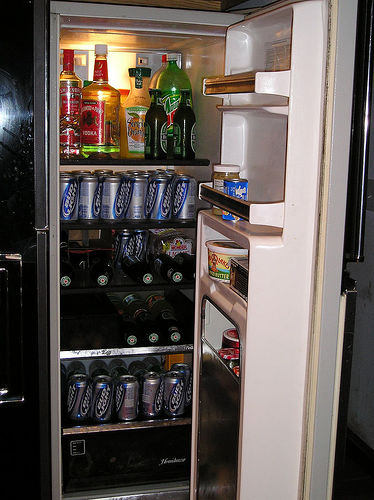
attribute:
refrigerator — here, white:
[6, 3, 372, 487]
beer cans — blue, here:
[61, 165, 202, 228]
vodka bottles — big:
[58, 35, 119, 168]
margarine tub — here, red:
[199, 233, 249, 291]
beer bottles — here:
[55, 248, 194, 292]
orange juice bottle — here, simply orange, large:
[116, 55, 160, 166]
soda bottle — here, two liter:
[147, 50, 195, 165]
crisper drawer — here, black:
[44, 415, 199, 492]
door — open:
[185, 2, 372, 492]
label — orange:
[116, 105, 156, 158]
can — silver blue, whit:
[127, 165, 157, 226]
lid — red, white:
[218, 343, 246, 363]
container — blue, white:
[224, 174, 254, 226]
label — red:
[62, 77, 81, 164]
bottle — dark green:
[171, 85, 204, 163]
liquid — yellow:
[121, 98, 140, 159]